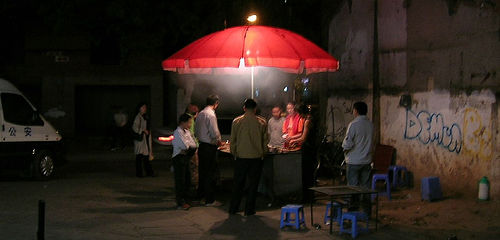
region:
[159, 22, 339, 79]
a red umbrella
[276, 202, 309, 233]
a blue stepping stool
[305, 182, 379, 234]
a small black table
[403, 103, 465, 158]
blue graffiti on the wall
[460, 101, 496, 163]
yellow graffiti on the wall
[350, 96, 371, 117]
the head of a man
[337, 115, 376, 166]
a gray jacket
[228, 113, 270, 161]
a tan jacket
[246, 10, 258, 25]
a yellow light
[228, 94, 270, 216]
a person standing under the umbrella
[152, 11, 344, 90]
red open umbrella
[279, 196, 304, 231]
small blue plastic chair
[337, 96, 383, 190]
man in a white jacket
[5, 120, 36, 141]
black Asian characters on a van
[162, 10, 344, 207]
people around a food cart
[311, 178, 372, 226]
small black table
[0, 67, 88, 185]
front of a white and black van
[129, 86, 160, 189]
woman with a black purse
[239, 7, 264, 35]
street lamp on top of an umbrella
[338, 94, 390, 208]
One person standing up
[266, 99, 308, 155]
Two people standing up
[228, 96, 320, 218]
Three people standing up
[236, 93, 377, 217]
four people standing up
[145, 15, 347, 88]
A large red umbrella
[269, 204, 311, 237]
A small blue stool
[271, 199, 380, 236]
Three small blue stools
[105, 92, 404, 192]
A bunch of people standing up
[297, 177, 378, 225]
A small table and blue stools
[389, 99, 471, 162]
Graffiti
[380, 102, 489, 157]
demon graffitied on the wall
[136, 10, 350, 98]
red umbrella with a light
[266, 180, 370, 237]
blue sitting stools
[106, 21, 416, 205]
people around a table with a red umbrella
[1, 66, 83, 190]
white and black van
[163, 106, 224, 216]
short man in white shirt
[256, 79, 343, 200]
people standing one wearing an orange shirt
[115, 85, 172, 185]
woman with a black purse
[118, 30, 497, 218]
a bunch of people hanging out by a graffiti covered wall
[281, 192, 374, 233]
three small blue stools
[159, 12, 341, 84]
The red umbrella above the people.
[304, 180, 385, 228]
The little black table in the middle of the blue chairs.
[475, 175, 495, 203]
The green and white jug against the cement wall.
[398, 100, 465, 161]
The blue graffiti on the wall.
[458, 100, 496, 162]
The yellow graffiti on the wall.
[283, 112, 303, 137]
The red scarf around the neck of the person under the umbrella.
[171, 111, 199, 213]
The lady in a white shirt and black pants.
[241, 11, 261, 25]
The street light above the red umbrella.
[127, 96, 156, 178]
The lady in a long gray coat holding a black purse.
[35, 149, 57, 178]
The front tire of the white and black van.